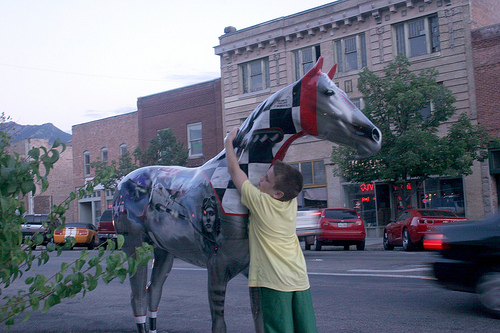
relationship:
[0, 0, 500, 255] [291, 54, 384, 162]
building has head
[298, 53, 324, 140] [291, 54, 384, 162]
stripe around head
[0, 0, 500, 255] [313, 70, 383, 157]
building has face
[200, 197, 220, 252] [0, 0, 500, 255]
person on building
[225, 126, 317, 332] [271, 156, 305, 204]
boy has hair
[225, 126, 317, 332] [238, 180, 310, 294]
boy wears shirt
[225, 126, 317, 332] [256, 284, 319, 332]
boy wears shorts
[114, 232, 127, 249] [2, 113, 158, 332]
leaf on tree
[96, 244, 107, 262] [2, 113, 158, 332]
leaf on tree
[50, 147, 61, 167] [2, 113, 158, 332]
leaf on tree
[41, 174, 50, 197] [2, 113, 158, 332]
leaf on tree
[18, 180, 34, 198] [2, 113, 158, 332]
leaf on tree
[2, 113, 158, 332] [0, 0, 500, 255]
tree near building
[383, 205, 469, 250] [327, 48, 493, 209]
car next to tree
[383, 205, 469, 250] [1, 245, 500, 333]
car across street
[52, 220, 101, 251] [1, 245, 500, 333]
car across street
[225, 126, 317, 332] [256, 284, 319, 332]
boy wearing shorts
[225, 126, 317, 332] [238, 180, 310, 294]
boy wearing shirt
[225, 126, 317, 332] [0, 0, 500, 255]
boy huge building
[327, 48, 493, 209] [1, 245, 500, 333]
tree next to street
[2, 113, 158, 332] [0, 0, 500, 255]
tree next to building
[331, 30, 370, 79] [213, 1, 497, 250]
window in building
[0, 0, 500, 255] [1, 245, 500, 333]
building on street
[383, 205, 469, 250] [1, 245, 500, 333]
car on street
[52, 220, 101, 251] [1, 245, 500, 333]
car on street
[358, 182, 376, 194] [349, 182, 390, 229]
sign in window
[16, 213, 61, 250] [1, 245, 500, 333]
car on street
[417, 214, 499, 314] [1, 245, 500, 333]
car on street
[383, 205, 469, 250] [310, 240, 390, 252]
car near curb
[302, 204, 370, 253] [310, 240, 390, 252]
car near curb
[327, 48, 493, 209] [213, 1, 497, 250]
tree in front of building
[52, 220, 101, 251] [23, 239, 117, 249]
car near curb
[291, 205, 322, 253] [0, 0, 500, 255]
pick-up truck behind building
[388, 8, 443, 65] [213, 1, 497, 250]
window in building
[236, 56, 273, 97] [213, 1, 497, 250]
window on building